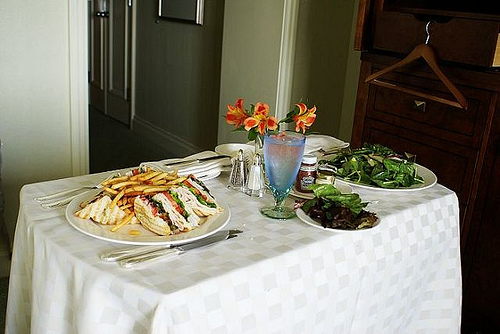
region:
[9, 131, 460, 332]
table with food and a vase on it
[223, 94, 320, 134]
flowers on the table with food on it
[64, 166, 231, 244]
a plate with french fries and sandwiches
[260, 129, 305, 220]
light blue glass with beverage in it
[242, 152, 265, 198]
salt shaker on the table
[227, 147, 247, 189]
pepper shaker on the table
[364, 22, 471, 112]
a wooden clothes hanger to the right of the table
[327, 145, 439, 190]
large white plate of greens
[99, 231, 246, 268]
silver utensils next to plate of sandwiches and french fries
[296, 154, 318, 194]
small bottle of ketchup on the table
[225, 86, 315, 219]
orange and red flowers on table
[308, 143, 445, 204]
a plate of greens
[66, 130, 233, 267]
a plate with fries and sandwich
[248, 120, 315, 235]
a glass of drinking water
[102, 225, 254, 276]
two knives next to plate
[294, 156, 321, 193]
a small bottle of Heinz ketchup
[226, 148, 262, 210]
a salt and pepper shaker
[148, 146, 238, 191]
a white napkin with knife on it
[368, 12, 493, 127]
a coat hanger on the chair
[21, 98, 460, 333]
a white table cloth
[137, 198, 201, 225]
a few finger sandwiches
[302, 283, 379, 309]
section of a patterned white table cloth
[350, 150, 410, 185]
tossed salad greens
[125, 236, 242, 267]
two knives next to a plate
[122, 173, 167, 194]
a display of gourmet french fries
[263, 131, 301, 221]
a glass of clear water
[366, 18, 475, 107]
a wooden coat hanger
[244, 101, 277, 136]
an orange and yellow flower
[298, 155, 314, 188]
a jar of a red condiment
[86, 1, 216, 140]
view down a darkened hallway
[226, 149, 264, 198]
Salt and pepper sit on the cart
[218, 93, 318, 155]
Flowers placed on the cart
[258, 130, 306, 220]
Large glass of water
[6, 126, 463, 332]
Food on service tray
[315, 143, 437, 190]
Plate of salad greens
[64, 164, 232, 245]
Sandwich and fries on the plate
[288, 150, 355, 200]
Condiments on the tray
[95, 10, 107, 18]
Silver knob on the door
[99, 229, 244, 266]
Knives on the tray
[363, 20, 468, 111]
Wooden hanger hangs on open drawer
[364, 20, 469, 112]
A wooden dress hanger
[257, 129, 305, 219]
A blue and green glass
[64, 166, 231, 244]
A white plate of sandwitches and fries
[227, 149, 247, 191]
A clear pepper shaker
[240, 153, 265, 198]
A clear salt shaker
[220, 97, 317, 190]
A clear vase with lillies in it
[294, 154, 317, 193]
A small container of Heinz ketchup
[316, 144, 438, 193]
A large plate of salad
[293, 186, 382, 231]
A small plate of salad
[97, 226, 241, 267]
A pair of silver serving knives